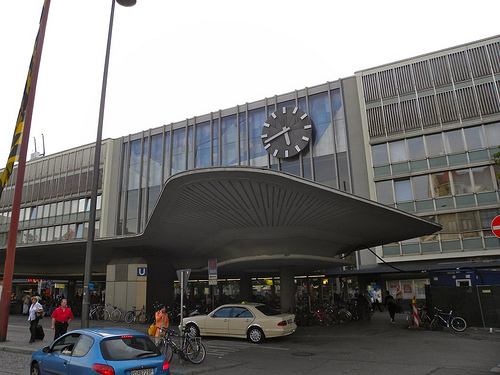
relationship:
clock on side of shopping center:
[252, 104, 342, 180] [18, 31, 493, 323]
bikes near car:
[155, 330, 209, 365] [44, 322, 179, 375]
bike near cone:
[419, 307, 465, 336] [408, 305, 425, 328]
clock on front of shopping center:
[252, 104, 342, 180] [18, 31, 493, 323]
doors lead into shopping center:
[177, 277, 362, 318] [18, 31, 493, 323]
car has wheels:
[189, 292, 282, 341] [242, 319, 270, 349]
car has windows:
[189, 292, 282, 341] [209, 294, 259, 326]